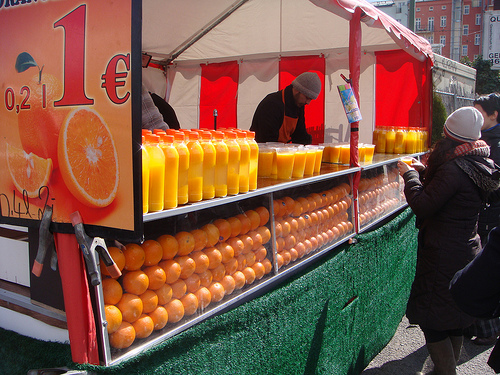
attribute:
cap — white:
[443, 105, 484, 142]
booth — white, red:
[26, 2, 434, 367]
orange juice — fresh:
[147, 119, 413, 181]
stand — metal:
[339, 11, 394, 195]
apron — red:
[269, 83, 303, 138]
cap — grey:
[284, 68, 331, 100]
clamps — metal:
[19, 199, 146, 356]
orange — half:
[125, 254, 216, 298]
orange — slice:
[331, 151, 345, 164]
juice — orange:
[171, 129, 197, 209]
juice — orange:
[256, 143, 326, 190]